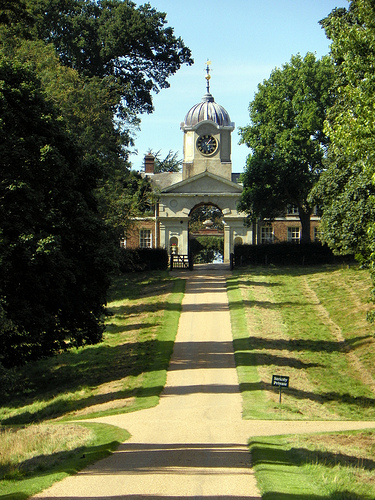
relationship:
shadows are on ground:
[4, 269, 374, 500] [2, 258, 375, 500]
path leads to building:
[34, 264, 262, 498] [117, 55, 324, 268]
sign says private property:
[269, 374, 290, 388] [272, 376, 287, 386]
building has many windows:
[117, 55, 324, 268] [119, 221, 320, 250]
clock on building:
[196, 133, 219, 156] [117, 55, 324, 268]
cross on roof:
[204, 56, 214, 74] [179, 96, 234, 134]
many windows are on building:
[119, 221, 320, 250] [117, 55, 324, 268]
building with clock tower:
[117, 55, 324, 268] [180, 100, 234, 177]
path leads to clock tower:
[34, 264, 262, 498] [180, 100, 234, 177]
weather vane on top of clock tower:
[202, 64, 212, 74] [180, 100, 234, 177]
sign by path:
[269, 374, 290, 388] [34, 264, 262, 498]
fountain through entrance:
[201, 217, 216, 231] [188, 205, 226, 267]